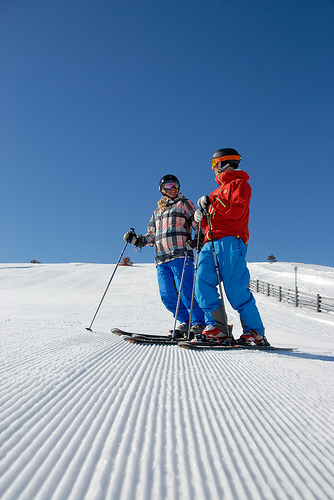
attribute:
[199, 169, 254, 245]
jacket — red, warm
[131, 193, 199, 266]
jacket — warm, plaid, colorful, striped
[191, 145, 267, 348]
person — discussing, happy, standing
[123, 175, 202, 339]
person — discussing, happy, standing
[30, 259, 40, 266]
building — small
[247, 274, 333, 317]
fence — wooden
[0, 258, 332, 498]
snow — machine-prepared, ridged, ground, lined, plowed, white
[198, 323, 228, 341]
boot — red, white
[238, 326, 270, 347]
boot — red, white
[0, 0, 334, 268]
sky — blue, cloudless, clear, deep blue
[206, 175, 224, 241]
zipper — yellow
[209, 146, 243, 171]
helmet — safe, black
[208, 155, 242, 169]
goggles — orange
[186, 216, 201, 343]
ski pole — needed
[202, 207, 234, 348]
ski pole — needed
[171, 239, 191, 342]
ski pole — needed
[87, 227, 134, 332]
ski pole — needed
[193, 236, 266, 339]
ski pants — blue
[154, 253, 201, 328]
ski pants — blue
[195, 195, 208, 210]
glove — white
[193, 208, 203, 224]
glove — white